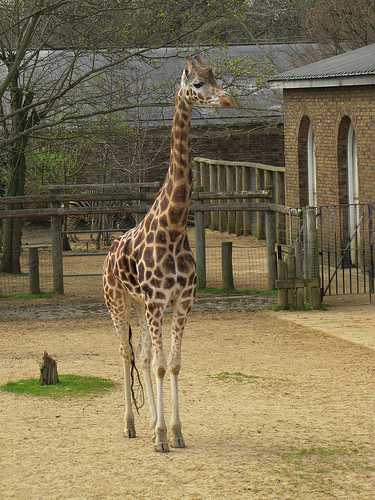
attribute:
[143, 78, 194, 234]
neck — long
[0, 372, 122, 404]
grass — green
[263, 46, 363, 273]
building — brick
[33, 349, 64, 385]
wood — small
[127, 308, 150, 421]
tail — black, long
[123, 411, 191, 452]
feet — thin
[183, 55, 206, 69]
horns — small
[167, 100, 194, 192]
neck — long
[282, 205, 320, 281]
wood fence — small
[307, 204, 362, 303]
gate — small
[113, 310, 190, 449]
legs — thin, long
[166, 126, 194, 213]
neck — long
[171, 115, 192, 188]
neck — long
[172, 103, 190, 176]
neck — long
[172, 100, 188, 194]
neck — long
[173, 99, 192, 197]
neck — long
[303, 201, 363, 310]
gate — closed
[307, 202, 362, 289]
gate — closed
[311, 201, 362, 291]
gate — closed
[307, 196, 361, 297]
gate — closed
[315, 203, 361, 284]
gate — closed